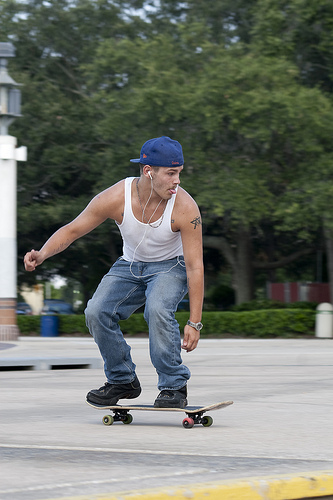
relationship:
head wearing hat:
[130, 136, 183, 199] [129, 135, 183, 166]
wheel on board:
[180, 417, 192, 427] [83, 398, 232, 413]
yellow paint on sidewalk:
[87, 477, 332, 496] [9, 362, 331, 493]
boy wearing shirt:
[23, 137, 204, 408] [113, 176, 183, 263]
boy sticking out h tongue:
[23, 137, 204, 408] [164, 186, 179, 194]